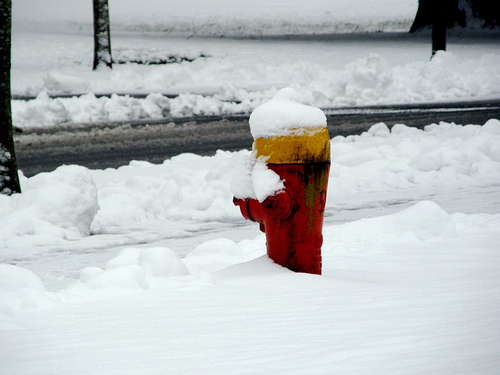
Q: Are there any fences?
A: No, there are no fences.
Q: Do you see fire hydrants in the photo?
A: Yes, there is a fire hydrant.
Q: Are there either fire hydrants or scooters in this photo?
A: Yes, there is a fire hydrant.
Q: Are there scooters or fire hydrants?
A: Yes, there is a fire hydrant.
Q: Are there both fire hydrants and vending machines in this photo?
A: No, there is a fire hydrant but no vending machines.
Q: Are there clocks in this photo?
A: No, there are no clocks.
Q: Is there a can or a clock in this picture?
A: No, there are no clocks or cans.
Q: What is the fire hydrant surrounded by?
A: The fire hydrant is surrounded by the snow.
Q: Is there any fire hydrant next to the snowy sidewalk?
A: Yes, there is a fire hydrant next to the side walk.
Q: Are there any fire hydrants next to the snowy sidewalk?
A: Yes, there is a fire hydrant next to the side walk.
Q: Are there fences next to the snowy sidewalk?
A: No, there is a fire hydrant next to the sidewalk.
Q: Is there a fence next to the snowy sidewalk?
A: No, there is a fire hydrant next to the sidewalk.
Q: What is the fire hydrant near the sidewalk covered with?
A: The fire hydrant is covered with snow.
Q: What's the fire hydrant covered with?
A: The fire hydrant is covered with snow.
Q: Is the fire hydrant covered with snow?
A: Yes, the fire hydrant is covered with snow.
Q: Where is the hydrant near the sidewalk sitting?
A: The fire hydrant is sitting in the snow.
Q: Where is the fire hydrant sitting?
A: The fire hydrant is sitting in the snow.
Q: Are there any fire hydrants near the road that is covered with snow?
A: Yes, there is a fire hydrant near the road.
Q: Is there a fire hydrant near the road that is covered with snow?
A: Yes, there is a fire hydrant near the road.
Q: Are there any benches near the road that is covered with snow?
A: No, there is a fire hydrant near the road.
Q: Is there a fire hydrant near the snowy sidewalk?
A: Yes, there is a fire hydrant near the sidewalk.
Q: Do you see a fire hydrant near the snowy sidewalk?
A: Yes, there is a fire hydrant near the sidewalk.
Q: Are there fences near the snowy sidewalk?
A: No, there is a fire hydrant near the sidewalk.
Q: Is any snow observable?
A: Yes, there is snow.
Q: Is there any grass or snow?
A: Yes, there is snow.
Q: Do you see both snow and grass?
A: No, there is snow but no grass.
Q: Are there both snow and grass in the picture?
A: No, there is snow but no grass.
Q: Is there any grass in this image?
A: No, there is no grass.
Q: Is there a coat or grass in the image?
A: No, there are no grass or coats.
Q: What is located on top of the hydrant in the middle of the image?
A: The snow is on top of the hydrant.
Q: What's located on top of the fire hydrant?
A: The snow is on top of the hydrant.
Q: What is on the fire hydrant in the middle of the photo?
A: The snow is on the hydrant.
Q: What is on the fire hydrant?
A: The snow is on the hydrant.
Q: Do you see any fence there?
A: No, there are no fences.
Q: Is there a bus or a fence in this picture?
A: No, there are no fences or buses.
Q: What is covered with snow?
A: The road is covered with snow.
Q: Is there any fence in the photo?
A: No, there are no fences.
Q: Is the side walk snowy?
A: Yes, the side walk is snowy.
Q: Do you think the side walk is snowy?
A: Yes, the side walk is snowy.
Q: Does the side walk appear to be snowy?
A: Yes, the side walk is snowy.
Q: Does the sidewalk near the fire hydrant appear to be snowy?
A: Yes, the sidewalk is snowy.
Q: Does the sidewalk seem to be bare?
A: No, the sidewalk is snowy.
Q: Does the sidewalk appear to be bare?
A: No, the sidewalk is snowy.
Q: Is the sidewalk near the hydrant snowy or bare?
A: The side walk is snowy.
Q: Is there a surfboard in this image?
A: No, there are no surfboards.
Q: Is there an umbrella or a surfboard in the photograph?
A: No, there are no surfboards or umbrellas.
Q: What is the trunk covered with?
A: The trunk is covered with snow.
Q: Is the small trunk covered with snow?
A: Yes, the trunk is covered with snow.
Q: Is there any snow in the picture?
A: Yes, there is snow.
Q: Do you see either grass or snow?
A: Yes, there is snow.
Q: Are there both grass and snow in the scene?
A: No, there is snow but no grass.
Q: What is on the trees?
A: The snow is on the trees.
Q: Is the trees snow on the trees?
A: Yes, the snow is on the trees.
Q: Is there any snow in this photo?
A: Yes, there is snow.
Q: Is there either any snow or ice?
A: Yes, there is snow.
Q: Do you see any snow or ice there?
A: Yes, there is snow.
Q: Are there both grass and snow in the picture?
A: No, there is snow but no grass.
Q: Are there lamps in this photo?
A: No, there are no lamps.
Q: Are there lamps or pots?
A: No, there are no lamps or pots.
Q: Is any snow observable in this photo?
A: Yes, there is snow.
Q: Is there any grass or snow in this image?
A: Yes, there is snow.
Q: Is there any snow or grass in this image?
A: Yes, there is snow.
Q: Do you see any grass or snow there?
A: Yes, there is snow.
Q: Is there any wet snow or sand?
A: Yes, there is wet snow.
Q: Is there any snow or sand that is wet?
A: Yes, the snow is wet.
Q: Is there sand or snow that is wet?
A: Yes, the snow is wet.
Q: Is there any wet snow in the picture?
A: Yes, there is wet snow.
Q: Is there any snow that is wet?
A: Yes, there is snow that is wet.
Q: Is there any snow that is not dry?
A: Yes, there is wet snow.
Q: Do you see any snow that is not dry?
A: Yes, there is wet snow.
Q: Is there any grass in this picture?
A: No, there is no grass.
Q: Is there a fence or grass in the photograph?
A: No, there are no grass or fences.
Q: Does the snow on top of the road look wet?
A: Yes, the snow is wet.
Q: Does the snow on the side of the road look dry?
A: No, the snow is wet.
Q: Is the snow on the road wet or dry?
A: The snow is wet.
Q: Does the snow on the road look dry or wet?
A: The snow is wet.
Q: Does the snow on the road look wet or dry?
A: The snow is wet.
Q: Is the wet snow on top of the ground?
A: Yes, the snow is on top of the ground.